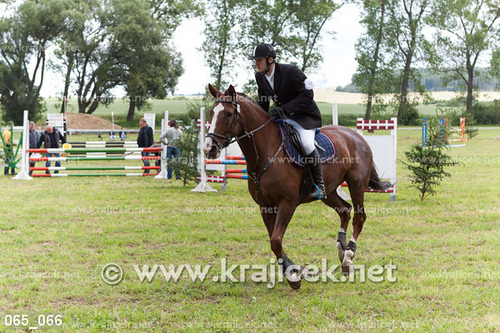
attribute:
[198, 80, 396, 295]
horse's — left ear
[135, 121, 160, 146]
jacket — black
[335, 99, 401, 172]
fence — red, white, checkered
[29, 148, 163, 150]
pole — red, white, green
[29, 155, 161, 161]
pole — green, white, red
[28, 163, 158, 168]
pole — green, white, red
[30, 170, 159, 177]
pole — green, white, red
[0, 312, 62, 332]
numbers — six, at the bottom of photo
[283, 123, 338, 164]
horse saddle — blue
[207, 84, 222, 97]
ear — little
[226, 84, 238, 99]
ear — little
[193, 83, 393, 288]
horse — right ear, brown, white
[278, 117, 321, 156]
pants — white 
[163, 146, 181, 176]
jeans — blue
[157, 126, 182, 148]
sweatshirt — gray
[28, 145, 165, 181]
poles — green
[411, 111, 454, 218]
tree — small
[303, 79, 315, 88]
patch — white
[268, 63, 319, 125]
jacket — black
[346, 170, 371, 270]
leg — brown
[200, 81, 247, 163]
head — brown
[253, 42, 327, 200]
man — on horseback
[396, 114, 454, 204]
tree — small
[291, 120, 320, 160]
pants — white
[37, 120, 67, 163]
coat — white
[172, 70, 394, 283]
horse — beautiful, brown